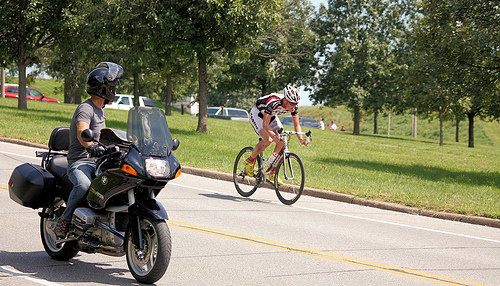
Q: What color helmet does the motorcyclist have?
A: Black.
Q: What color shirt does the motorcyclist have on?
A: Gray.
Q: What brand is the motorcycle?
A: BMW.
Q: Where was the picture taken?
A: On a street.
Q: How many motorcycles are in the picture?
A: 1.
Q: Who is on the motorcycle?
A: A man.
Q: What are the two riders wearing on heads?
A: Helmets.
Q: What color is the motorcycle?
A: Black.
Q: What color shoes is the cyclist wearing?
A: Yellow.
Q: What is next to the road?
A: Grass.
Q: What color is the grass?
A: Green.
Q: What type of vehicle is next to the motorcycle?
A: A bicycle.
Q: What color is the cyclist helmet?
A: White.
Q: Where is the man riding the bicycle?
A: Street.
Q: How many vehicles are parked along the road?
A: Four.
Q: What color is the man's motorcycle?
A: Black.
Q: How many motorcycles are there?
A: One.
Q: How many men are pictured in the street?
A: Two.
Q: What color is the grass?
A: Green.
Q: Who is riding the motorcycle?
A: A man.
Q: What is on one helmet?
A: A visor.